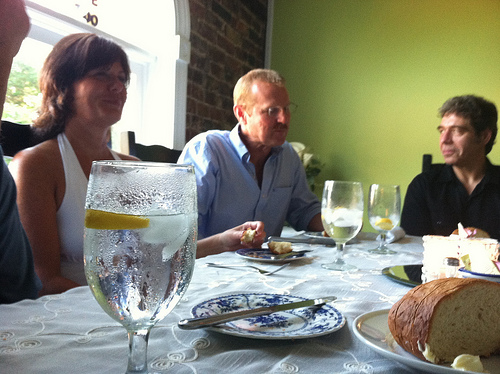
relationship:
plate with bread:
[352, 306, 499, 371] [389, 276, 499, 372]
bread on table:
[389, 277, 499, 359] [0, 226, 498, 372]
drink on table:
[320, 180, 363, 270] [0, 226, 498, 372]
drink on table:
[367, 183, 401, 253] [0, 226, 498, 372]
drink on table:
[84, 159, 196, 372] [0, 226, 498, 372]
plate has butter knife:
[202, 227, 309, 359] [174, 294, 340, 330]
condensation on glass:
[85, 166, 199, 327] [85, 156, 202, 368]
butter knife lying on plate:
[174, 294, 340, 328] [190, 291, 346, 340]